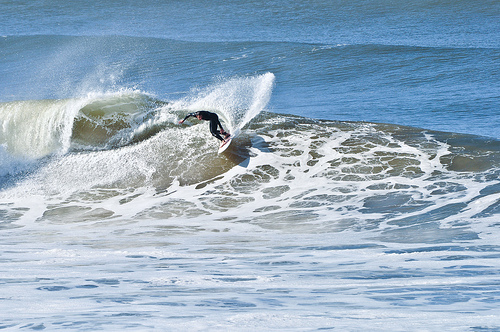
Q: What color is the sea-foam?
A: White.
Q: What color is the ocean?
A: Blue.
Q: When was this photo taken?
A: Outside, during the daytime.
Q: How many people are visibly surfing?
A: One.